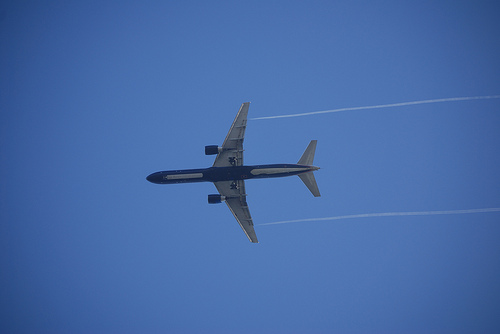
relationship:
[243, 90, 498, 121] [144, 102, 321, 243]
smoke trailing behind airplane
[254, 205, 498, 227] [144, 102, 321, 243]
smoke trailing behind airplane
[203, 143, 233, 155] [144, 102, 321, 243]
engine on airplane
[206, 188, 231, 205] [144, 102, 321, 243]
engine on airplane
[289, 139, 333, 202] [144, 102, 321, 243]
tail on airplane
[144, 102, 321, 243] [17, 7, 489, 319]
airplane in sky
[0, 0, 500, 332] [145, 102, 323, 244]
sky above airplane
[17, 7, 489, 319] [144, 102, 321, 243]
sky around airplane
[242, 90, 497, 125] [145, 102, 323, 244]
streamer behind airplane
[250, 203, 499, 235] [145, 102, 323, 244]
streamer behind airplane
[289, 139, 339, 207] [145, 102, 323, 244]
tail on airplane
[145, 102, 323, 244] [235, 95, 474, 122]
airplane emits smoke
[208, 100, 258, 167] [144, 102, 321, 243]
wing on airplane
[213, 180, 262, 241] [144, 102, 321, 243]
wing on airplane